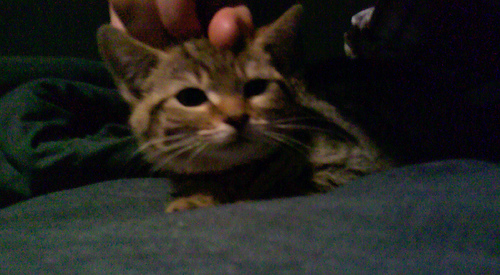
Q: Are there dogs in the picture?
A: No, there are no dogs.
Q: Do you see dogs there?
A: No, there are no dogs.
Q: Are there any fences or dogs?
A: No, there are no dogs or fences.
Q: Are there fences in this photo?
A: No, there are no fences.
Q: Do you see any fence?
A: No, there are no fences.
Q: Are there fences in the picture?
A: No, there are no fences.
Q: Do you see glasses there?
A: No, there are no glasses.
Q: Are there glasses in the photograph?
A: No, there are no glasses.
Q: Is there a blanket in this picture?
A: Yes, there is a blanket.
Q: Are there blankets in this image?
A: Yes, there is a blanket.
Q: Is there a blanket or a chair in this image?
A: Yes, there is a blanket.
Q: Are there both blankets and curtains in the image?
A: No, there is a blanket but no curtains.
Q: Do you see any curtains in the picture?
A: No, there are no curtains.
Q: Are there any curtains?
A: No, there are no curtains.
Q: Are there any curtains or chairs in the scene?
A: No, there are no curtains or chairs.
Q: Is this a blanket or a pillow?
A: This is a blanket.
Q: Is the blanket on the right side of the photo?
A: No, the blanket is on the left of the image.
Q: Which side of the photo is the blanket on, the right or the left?
A: The blanket is on the left of the image.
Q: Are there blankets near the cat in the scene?
A: Yes, there is a blanket near the cat.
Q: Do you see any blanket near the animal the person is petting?
A: Yes, there is a blanket near the cat.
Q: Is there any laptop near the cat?
A: No, there is a blanket near the cat.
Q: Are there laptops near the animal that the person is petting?
A: No, there is a blanket near the cat.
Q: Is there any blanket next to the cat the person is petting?
A: Yes, there is a blanket next to the cat.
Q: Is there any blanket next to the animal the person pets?
A: Yes, there is a blanket next to the cat.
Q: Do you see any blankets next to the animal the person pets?
A: Yes, there is a blanket next to the cat.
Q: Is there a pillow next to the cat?
A: No, there is a blanket next to the cat.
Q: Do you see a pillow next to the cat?
A: No, there is a blanket next to the cat.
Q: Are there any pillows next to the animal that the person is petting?
A: No, there is a blanket next to the cat.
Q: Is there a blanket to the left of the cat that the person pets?
A: Yes, there is a blanket to the left of the cat.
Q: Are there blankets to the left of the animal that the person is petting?
A: Yes, there is a blanket to the left of the cat.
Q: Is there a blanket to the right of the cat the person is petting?
A: No, the blanket is to the left of the cat.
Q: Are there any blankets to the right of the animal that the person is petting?
A: No, the blanket is to the left of the cat.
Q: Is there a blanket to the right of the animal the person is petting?
A: No, the blanket is to the left of the cat.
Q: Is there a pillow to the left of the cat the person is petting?
A: No, there is a blanket to the left of the cat.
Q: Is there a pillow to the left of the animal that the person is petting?
A: No, there is a blanket to the left of the cat.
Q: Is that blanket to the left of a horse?
A: No, the blanket is to the left of the cat.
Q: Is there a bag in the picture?
A: No, there are no bags.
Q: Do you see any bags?
A: No, there are no bags.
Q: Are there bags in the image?
A: No, there are no bags.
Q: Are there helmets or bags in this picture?
A: No, there are no bags or helmets.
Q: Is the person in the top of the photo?
A: Yes, the person is in the top of the image.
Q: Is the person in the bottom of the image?
A: No, the person is in the top of the image.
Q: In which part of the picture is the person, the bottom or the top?
A: The person is in the top of the image.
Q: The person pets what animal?
A: The person pets the cat.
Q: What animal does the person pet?
A: The person pets the cat.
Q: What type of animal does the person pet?
A: The person pets the cat.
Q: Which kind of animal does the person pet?
A: The person pets the cat.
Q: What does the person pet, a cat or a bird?
A: The person pets a cat.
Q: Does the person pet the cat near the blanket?
A: Yes, the person pets the cat.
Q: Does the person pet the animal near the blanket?
A: Yes, the person pets the cat.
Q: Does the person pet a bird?
A: No, the person pets the cat.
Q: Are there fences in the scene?
A: No, there are no fences.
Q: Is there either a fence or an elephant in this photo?
A: No, there are no fences or elephants.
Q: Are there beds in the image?
A: Yes, there is a bed.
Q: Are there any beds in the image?
A: Yes, there is a bed.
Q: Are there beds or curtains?
A: Yes, there is a bed.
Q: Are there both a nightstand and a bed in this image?
A: No, there is a bed but no nightstands.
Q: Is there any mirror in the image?
A: No, there are no mirrors.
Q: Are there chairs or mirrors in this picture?
A: No, there are no mirrors or chairs.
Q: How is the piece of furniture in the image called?
A: The piece of furniture is a bed.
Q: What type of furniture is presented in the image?
A: The furniture is a bed.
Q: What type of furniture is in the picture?
A: The furniture is a bed.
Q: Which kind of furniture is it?
A: The piece of furniture is a bed.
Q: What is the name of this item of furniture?
A: This is a bed.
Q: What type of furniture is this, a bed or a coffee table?
A: This is a bed.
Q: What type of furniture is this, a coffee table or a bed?
A: This is a bed.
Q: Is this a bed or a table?
A: This is a bed.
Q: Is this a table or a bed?
A: This is a bed.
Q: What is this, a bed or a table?
A: This is a bed.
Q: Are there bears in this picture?
A: No, there are no bears.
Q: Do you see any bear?
A: No, there are no bears.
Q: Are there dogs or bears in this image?
A: No, there are no bears or dogs.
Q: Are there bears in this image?
A: No, there are no bears.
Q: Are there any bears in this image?
A: No, there are no bears.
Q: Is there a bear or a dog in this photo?
A: No, there are no bears or dogs.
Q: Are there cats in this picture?
A: Yes, there is a cat.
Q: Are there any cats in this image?
A: Yes, there is a cat.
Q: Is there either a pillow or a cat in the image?
A: Yes, there is a cat.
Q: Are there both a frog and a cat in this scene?
A: No, there is a cat but no frogs.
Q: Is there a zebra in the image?
A: No, there are no zebras.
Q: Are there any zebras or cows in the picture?
A: No, there are no zebras or cows.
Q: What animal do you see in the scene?
A: The animal is a cat.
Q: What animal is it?
A: The animal is a cat.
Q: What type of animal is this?
A: This is a cat.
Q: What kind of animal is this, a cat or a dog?
A: This is a cat.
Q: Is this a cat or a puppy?
A: This is a cat.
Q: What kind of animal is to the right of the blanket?
A: The animal is a cat.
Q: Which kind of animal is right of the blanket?
A: The animal is a cat.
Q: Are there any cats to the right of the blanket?
A: Yes, there is a cat to the right of the blanket.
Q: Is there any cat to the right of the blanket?
A: Yes, there is a cat to the right of the blanket.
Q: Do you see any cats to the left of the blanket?
A: No, the cat is to the right of the blanket.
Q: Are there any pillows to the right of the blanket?
A: No, there is a cat to the right of the blanket.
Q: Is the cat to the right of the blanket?
A: Yes, the cat is to the right of the blanket.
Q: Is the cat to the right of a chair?
A: No, the cat is to the right of the blanket.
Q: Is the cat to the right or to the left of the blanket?
A: The cat is to the right of the blanket.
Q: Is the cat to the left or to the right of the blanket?
A: The cat is to the right of the blanket.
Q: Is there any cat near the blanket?
A: Yes, there is a cat near the blanket.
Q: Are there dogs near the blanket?
A: No, there is a cat near the blanket.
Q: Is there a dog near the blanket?
A: No, there is a cat near the blanket.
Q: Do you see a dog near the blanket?
A: No, there is a cat near the blanket.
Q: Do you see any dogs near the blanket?
A: No, there is a cat near the blanket.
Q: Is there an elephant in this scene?
A: No, there are no elephants.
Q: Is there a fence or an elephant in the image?
A: No, there are no elephants or fences.